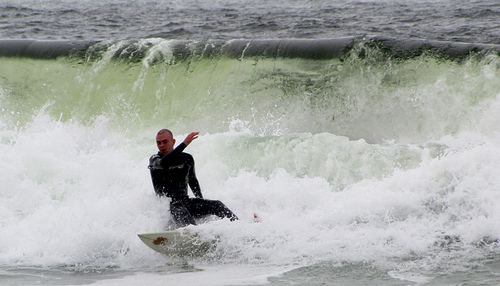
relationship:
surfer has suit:
[147, 129, 240, 227] [146, 152, 240, 226]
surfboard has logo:
[135, 231, 217, 256] [153, 236, 169, 248]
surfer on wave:
[147, 129, 240, 227] [1, 39, 497, 265]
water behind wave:
[1, 1, 499, 45] [1, 39, 497, 265]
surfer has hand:
[147, 129, 240, 227] [182, 131, 200, 145]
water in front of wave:
[0, 255, 498, 284] [1, 39, 497, 265]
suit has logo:
[146, 152, 240, 226] [169, 164, 184, 171]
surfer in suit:
[147, 129, 240, 227] [146, 152, 240, 226]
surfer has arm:
[147, 129, 240, 227] [150, 130, 199, 168]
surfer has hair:
[147, 129, 240, 227] [157, 129, 174, 140]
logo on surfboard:
[153, 236, 169, 248] [135, 231, 217, 256]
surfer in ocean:
[147, 129, 240, 227] [1, 2, 498, 283]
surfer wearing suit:
[147, 129, 240, 227] [146, 152, 240, 226]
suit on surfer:
[146, 152, 240, 226] [147, 129, 240, 227]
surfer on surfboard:
[147, 129, 240, 227] [135, 231, 217, 256]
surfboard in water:
[135, 231, 217, 256] [0, 255, 498, 284]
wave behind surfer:
[1, 39, 497, 265] [147, 129, 240, 227]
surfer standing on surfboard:
[147, 129, 240, 227] [135, 231, 217, 256]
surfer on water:
[147, 129, 240, 227] [0, 255, 498, 284]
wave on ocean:
[1, 39, 497, 265] [1, 2, 498, 283]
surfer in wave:
[147, 129, 240, 227] [1, 39, 497, 265]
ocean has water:
[1, 2, 498, 283] [1, 1, 499, 45]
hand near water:
[182, 131, 200, 145] [0, 255, 498, 284]